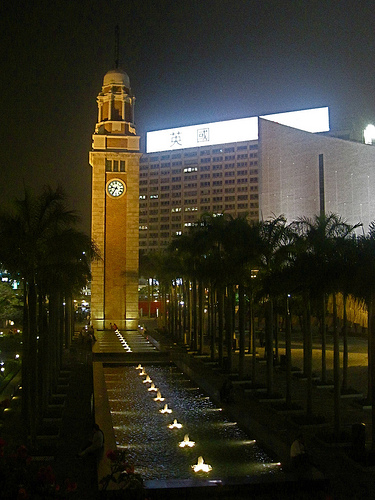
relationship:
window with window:
[148, 192, 159, 198] [183, 165, 198, 170]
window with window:
[148, 192, 159, 198] [171, 205, 184, 212]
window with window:
[148, 192, 159, 198] [139, 193, 145, 199]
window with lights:
[148, 192, 159, 198] [177, 162, 199, 222]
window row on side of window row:
[138, 142, 257, 163] [136, 152, 258, 171]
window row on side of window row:
[138, 142, 257, 163] [136, 160, 257, 179]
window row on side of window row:
[138, 142, 257, 163] [137, 166, 258, 186]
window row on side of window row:
[138, 142, 257, 163] [138, 175, 258, 193]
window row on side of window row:
[138, 142, 257, 163] [139, 183, 258, 200]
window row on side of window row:
[138, 142, 257, 163] [137, 191, 258, 209]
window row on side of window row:
[138, 142, 257, 163] [136, 199, 260, 216]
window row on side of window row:
[138, 142, 257, 163] [136, 209, 257, 224]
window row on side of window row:
[138, 142, 257, 163] [136, 218, 256, 231]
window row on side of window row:
[138, 142, 257, 163] [136, 230, 187, 239]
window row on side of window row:
[138, 142, 257, 163] [135, 238, 175, 247]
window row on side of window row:
[138, 142, 257, 163] [136, 247, 168, 257]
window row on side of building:
[138, 142, 257, 163] [140, 102, 341, 357]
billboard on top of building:
[139, 111, 353, 159] [140, 110, 363, 271]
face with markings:
[107, 179, 124, 197] [108, 181, 120, 193]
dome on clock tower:
[86, 58, 141, 149] [93, 67, 152, 204]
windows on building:
[106, 159, 126, 175] [85, 23, 144, 331]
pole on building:
[109, 24, 123, 69] [85, 23, 144, 331]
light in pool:
[133, 360, 144, 370] [97, 358, 290, 486]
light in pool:
[136, 367, 150, 376] [97, 358, 290, 486]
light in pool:
[150, 388, 168, 405] [97, 358, 290, 486]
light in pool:
[166, 416, 186, 429] [97, 358, 290, 486]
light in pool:
[174, 431, 197, 448] [97, 358, 290, 486]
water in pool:
[130, 382, 153, 447] [86, 319, 306, 500]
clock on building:
[104, 173, 128, 201] [80, 64, 153, 334]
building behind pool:
[78, 90, 166, 328] [83, 306, 314, 500]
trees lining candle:
[139, 211, 373, 444] [191, 454, 213, 474]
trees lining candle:
[139, 211, 373, 444] [178, 430, 196, 448]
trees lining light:
[139, 211, 373, 444] [167, 417, 183, 430]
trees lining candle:
[139, 211, 373, 444] [159, 403, 172, 414]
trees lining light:
[139, 211, 373, 444] [153, 389, 167, 402]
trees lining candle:
[0, 175, 99, 453] [191, 454, 213, 474]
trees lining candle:
[0, 175, 99, 453] [178, 430, 196, 448]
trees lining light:
[0, 175, 99, 453] [167, 417, 183, 430]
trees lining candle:
[0, 175, 99, 453] [159, 403, 172, 414]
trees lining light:
[0, 175, 99, 453] [153, 389, 167, 402]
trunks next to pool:
[167, 285, 373, 400] [94, 331, 267, 485]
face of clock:
[107, 177, 121, 199] [106, 181, 125, 197]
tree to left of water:
[23, 248, 54, 392] [88, 333, 293, 480]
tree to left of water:
[45, 254, 66, 373] [88, 333, 293, 480]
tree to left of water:
[51, 232, 107, 360] [88, 333, 293, 480]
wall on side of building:
[257, 117, 373, 233] [130, 123, 363, 314]